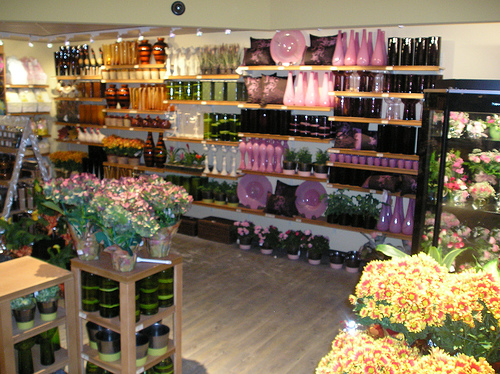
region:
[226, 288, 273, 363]
There is a brown floor that is visible here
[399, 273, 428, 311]
There are some yellow and red flowers here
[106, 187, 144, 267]
There is a pink plant that is visible here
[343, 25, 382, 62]
There are some pink vases that are visible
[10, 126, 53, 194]
There is a ladder that is visible here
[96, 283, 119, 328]
There are jars of body cream visible here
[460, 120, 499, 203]
There is a cold case of flowers visible here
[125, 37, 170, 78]
There are brown vases visible here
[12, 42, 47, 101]
There are pink and white items visible here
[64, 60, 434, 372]
Jackson Mingus took this photo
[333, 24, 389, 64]
pink vases on the shelf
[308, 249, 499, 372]
bunches of orange and yellow flowers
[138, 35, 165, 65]
orange and black vases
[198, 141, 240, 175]
white vases on the shelf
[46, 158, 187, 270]
pots of plants with purple flowers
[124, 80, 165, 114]
translucent amber vases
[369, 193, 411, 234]
lavender vases on the shelf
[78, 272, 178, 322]
black vases with green stripes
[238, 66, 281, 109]
shiny pink pillows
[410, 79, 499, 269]
glass case of flowers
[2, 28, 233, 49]
row of white lights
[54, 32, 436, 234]
glassware on wood shelves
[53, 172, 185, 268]
plants in three pots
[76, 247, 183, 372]
sqaure table with shelves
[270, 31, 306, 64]
pink plate on top shelf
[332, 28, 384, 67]
pink vases with long necks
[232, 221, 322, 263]
potted flowers on floor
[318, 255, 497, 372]
red and yellow flowers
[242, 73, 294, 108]
two pillows on shelf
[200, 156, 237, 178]
white vases on shelf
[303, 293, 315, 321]
part of the floor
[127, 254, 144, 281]
part of a shelf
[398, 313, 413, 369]
part of a flower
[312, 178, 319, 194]
part of a plate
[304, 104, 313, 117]
edge of a plate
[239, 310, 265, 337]
edge of a floor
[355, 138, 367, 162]
edge of a vase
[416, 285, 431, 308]
part of a flower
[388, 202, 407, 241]
Purple vase on shelf.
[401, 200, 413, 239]
Purple vase on shelf.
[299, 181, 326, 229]
Purple plate on shelf.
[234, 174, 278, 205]
Purple plate on shelf.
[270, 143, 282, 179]
Pink vase on shelf.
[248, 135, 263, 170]
Pink vase on shelf.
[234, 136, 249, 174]
Pink vase on shelf.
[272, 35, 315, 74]
Pink plate on shelf.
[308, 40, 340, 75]
Black and pink pillow on shelf.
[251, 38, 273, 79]
Black and pink pillows on shelf.